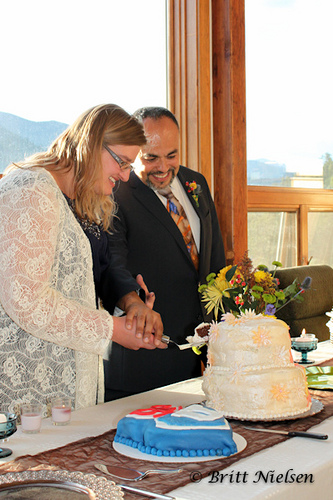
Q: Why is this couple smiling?
A: Married.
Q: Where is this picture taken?
A: Wedding.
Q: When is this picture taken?
A: Cutting cake.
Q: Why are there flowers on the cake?
A: Wedding.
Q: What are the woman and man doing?
A: Cutting cake.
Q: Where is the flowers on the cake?
A: Top.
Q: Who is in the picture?
A: A bride and groom.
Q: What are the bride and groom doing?
A: Cutting a cake.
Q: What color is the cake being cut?
A: White.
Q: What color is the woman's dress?
A: White.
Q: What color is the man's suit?
A: Black.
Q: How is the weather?
A: Sunny.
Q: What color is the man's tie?
A: Multi-colored.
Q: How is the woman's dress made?
A: Of lace.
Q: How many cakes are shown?
A: Two.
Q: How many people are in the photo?
A: 2.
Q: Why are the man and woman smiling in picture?
A: Just married.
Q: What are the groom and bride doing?
A: Cutting a wedding cake.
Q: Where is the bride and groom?
A: Reception room.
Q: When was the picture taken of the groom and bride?
A: Wedding day.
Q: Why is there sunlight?
A: It is daytime.